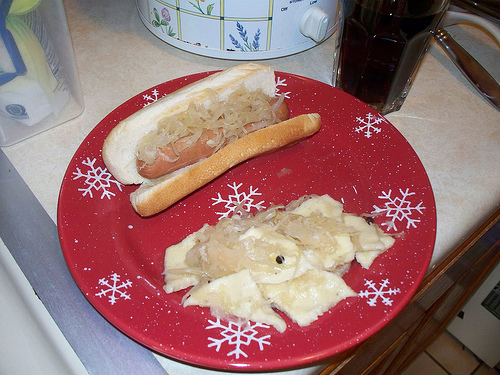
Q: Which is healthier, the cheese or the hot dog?
A: The cheese is healthier than the hot dog.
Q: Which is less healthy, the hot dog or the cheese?
A: The hot dog is less healthy than the cheese.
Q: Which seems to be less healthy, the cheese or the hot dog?
A: The hot dog is less healthy than the cheese.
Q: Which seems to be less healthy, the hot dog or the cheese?
A: The hot dog is less healthy than the cheese.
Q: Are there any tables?
A: Yes, there is a table.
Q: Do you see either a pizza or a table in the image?
A: Yes, there is a table.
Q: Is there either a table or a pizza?
A: Yes, there is a table.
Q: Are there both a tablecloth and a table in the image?
A: No, there is a table but no tablecloths.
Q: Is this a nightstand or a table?
A: This is a table.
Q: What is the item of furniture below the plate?
A: The piece of furniture is a table.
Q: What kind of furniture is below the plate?
A: The piece of furniture is a table.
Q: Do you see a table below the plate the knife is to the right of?
A: Yes, there is a table below the plate.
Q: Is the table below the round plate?
A: Yes, the table is below the plate.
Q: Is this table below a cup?
A: No, the table is below the plate.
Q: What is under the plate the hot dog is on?
A: The table is under the plate.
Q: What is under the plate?
A: The table is under the plate.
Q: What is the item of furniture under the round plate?
A: The piece of furniture is a table.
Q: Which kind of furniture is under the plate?
A: The piece of furniture is a table.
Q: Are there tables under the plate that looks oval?
A: Yes, there is a table under the plate.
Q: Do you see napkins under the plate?
A: No, there is a table under the plate.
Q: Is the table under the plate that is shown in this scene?
A: Yes, the table is under the plate.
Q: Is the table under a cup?
A: No, the table is under the plate.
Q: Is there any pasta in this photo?
A: Yes, there is pasta.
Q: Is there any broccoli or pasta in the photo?
A: Yes, there is pasta.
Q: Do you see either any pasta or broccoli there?
A: Yes, there is pasta.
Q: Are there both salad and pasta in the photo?
A: No, there is pasta but no salad.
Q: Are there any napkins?
A: No, there are no napkins.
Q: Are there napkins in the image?
A: No, there are no napkins.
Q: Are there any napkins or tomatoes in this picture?
A: No, there are no napkins or tomatoes.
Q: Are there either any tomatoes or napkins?
A: No, there are no napkins or tomatoes.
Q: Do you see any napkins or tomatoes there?
A: No, there are no napkins or tomatoes.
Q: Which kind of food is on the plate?
A: The food is pasta.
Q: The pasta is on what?
A: The pasta is on the plate.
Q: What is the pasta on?
A: The pasta is on the plate.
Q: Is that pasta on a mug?
A: No, the pasta is on the plate.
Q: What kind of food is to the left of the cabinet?
A: The food is pasta.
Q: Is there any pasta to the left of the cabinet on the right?
A: Yes, there is pasta to the left of the cabinet.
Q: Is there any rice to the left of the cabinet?
A: No, there is pasta to the left of the cabinet.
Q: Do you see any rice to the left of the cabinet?
A: No, there is pasta to the left of the cabinet.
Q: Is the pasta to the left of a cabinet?
A: Yes, the pasta is to the left of a cabinet.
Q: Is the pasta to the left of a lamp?
A: No, the pasta is to the left of a cabinet.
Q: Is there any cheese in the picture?
A: Yes, there is cheese.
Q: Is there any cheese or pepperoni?
A: Yes, there is cheese.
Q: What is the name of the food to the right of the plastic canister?
A: The food is cheese.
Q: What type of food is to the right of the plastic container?
A: The food is cheese.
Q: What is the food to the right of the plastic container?
A: The food is cheese.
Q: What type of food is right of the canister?
A: The food is cheese.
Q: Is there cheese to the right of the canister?
A: Yes, there is cheese to the right of the canister.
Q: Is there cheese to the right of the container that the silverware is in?
A: Yes, there is cheese to the right of the canister.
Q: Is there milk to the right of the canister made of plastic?
A: No, there is cheese to the right of the canister.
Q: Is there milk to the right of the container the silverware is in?
A: No, there is cheese to the right of the canister.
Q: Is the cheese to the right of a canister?
A: Yes, the cheese is to the right of a canister.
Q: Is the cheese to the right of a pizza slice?
A: No, the cheese is to the right of a canister.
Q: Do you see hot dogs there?
A: Yes, there is a hot dog.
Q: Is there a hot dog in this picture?
A: Yes, there is a hot dog.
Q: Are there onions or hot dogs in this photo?
A: Yes, there is a hot dog.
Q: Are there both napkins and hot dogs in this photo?
A: No, there is a hot dog but no napkins.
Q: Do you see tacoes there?
A: No, there are no tacoes.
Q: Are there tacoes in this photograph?
A: No, there are no tacoes.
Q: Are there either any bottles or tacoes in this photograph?
A: No, there are no tacoes or bottles.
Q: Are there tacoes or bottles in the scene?
A: No, there are no tacoes or bottles.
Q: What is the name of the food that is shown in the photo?
A: The food is a hot dog.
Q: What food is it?
A: The food is a hot dog.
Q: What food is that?
A: This is a hot dog.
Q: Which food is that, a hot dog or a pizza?
A: This is a hot dog.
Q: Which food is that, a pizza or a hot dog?
A: This is a hot dog.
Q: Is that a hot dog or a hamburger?
A: That is a hot dog.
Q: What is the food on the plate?
A: The food is a hot dog.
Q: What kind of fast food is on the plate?
A: The food is a hot dog.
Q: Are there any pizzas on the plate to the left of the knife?
A: No, there is a hot dog on the plate.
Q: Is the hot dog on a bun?
A: No, the hot dog is on the plate.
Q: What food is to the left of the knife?
A: The food is a hot dog.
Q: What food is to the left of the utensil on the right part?
A: The food is a hot dog.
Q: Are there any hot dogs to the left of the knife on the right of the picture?
A: Yes, there is a hot dog to the left of the knife.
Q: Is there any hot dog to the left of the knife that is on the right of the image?
A: Yes, there is a hot dog to the left of the knife.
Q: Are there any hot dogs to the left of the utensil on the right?
A: Yes, there is a hot dog to the left of the knife.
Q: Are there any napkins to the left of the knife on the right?
A: No, there is a hot dog to the left of the knife.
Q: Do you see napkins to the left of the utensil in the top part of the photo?
A: No, there is a hot dog to the left of the knife.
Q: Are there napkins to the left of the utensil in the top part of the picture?
A: No, there is a hot dog to the left of the knife.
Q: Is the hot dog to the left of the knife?
A: Yes, the hot dog is to the left of the knife.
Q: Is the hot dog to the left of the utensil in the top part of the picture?
A: Yes, the hot dog is to the left of the knife.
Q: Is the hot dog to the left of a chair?
A: No, the hot dog is to the left of the knife.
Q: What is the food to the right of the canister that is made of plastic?
A: The food is a hot dog.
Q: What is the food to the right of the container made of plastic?
A: The food is a hot dog.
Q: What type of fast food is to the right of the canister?
A: The food is a hot dog.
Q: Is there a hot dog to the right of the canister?
A: Yes, there is a hot dog to the right of the canister.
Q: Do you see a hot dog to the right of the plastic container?
A: Yes, there is a hot dog to the right of the canister.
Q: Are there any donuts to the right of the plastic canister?
A: No, there is a hot dog to the right of the canister.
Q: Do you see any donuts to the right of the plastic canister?
A: No, there is a hot dog to the right of the canister.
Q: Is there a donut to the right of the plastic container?
A: No, there is a hot dog to the right of the canister.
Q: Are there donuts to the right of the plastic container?
A: No, there is a hot dog to the right of the canister.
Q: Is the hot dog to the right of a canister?
A: Yes, the hot dog is to the right of a canister.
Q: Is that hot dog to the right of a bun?
A: No, the hot dog is to the right of a canister.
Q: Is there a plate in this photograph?
A: Yes, there is a plate.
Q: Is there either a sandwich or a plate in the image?
A: Yes, there is a plate.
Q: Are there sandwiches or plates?
A: Yes, there is a plate.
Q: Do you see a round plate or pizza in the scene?
A: Yes, there is a round plate.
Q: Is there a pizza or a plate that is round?
A: Yes, the plate is round.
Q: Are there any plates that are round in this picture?
A: Yes, there is a round plate.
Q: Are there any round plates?
A: Yes, there is a round plate.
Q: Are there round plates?
A: Yes, there is a round plate.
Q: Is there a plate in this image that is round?
A: Yes, there is a plate that is round.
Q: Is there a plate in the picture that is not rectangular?
A: Yes, there is a round plate.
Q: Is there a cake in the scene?
A: No, there are no cakes.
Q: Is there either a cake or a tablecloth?
A: No, there are no cakes or tablecloths.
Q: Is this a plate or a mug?
A: This is a plate.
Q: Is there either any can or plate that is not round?
A: No, there is a plate but it is round.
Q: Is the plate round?
A: Yes, the plate is round.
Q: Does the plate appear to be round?
A: Yes, the plate is round.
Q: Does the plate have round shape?
A: Yes, the plate is round.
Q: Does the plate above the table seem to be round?
A: Yes, the plate is round.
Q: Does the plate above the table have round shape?
A: Yes, the plate is round.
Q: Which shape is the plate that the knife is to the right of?
A: The plate is round.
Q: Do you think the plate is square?
A: No, the plate is round.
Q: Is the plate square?
A: No, the plate is round.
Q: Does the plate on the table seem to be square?
A: No, the plate is round.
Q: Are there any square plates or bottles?
A: No, there is a plate but it is round.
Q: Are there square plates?
A: No, there is a plate but it is round.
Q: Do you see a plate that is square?
A: No, there is a plate but it is round.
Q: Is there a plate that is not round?
A: No, there is a plate but it is round.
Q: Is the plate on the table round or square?
A: The plate is round.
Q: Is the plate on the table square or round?
A: The plate is round.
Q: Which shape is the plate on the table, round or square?
A: The plate is round.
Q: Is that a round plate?
A: Yes, that is a round plate.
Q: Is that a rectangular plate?
A: No, that is a round plate.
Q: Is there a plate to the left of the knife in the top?
A: Yes, there is a plate to the left of the knife.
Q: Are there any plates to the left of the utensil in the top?
A: Yes, there is a plate to the left of the knife.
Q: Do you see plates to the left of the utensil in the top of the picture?
A: Yes, there is a plate to the left of the knife.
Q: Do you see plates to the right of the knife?
A: No, the plate is to the left of the knife.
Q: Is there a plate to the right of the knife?
A: No, the plate is to the left of the knife.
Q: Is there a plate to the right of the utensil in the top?
A: No, the plate is to the left of the knife.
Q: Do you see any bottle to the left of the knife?
A: No, there is a plate to the left of the knife.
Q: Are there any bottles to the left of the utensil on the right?
A: No, there is a plate to the left of the knife.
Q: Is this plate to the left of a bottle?
A: No, the plate is to the left of a knife.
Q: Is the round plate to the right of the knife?
A: No, the plate is to the left of the knife.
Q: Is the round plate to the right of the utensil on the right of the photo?
A: No, the plate is to the left of the knife.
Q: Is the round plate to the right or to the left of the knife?
A: The plate is to the left of the knife.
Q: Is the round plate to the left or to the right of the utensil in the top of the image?
A: The plate is to the left of the knife.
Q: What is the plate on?
A: The plate is on the table.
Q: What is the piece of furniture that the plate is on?
A: The piece of furniture is a table.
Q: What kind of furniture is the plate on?
A: The plate is on the table.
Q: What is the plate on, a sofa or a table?
A: The plate is on a table.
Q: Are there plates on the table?
A: Yes, there is a plate on the table.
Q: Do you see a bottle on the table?
A: No, there is a plate on the table.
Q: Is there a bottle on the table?
A: No, there is a plate on the table.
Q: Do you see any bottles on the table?
A: No, there is a plate on the table.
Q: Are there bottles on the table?
A: No, there is a plate on the table.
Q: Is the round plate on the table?
A: Yes, the plate is on the table.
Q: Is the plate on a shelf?
A: No, the plate is on the table.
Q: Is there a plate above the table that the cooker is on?
A: Yes, there is a plate above the table.